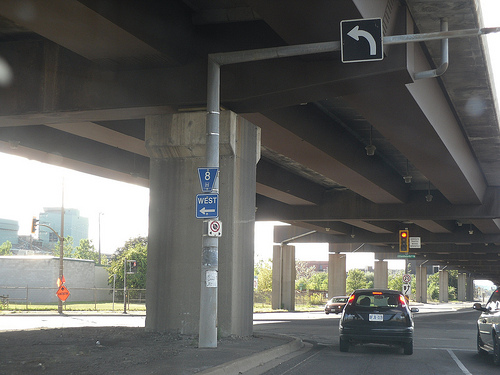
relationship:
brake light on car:
[390, 310, 415, 325] [321, 287, 452, 352]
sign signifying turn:
[334, 17, 389, 61] [438, 281, 498, 297]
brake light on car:
[372, 291, 382, 295] [345, 297, 412, 346]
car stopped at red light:
[336, 282, 434, 359] [396, 225, 406, 240]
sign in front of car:
[207, 217, 224, 237] [335, 287, 415, 355]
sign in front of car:
[193, 189, 216, 219] [472, 285, 498, 363]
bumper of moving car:
[341, 325, 415, 334] [466, 283, 498, 360]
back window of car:
[354, 291, 405, 310] [335, 287, 415, 355]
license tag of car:
[369, 313, 386, 325] [322, 285, 418, 357]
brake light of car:
[372, 291, 384, 296] [339, 288, 414, 353]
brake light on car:
[398, 294, 406, 306] [320, 270, 428, 367]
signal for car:
[390, 216, 416, 257] [313, 267, 430, 354]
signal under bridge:
[399, 229, 409, 252] [2, 1, 499, 338]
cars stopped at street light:
[323, 287, 498, 368] [400, 227, 407, 239]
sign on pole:
[54, 276, 71, 304] [56, 249, 64, 273]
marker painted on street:
[428, 338, 477, 366] [402, 280, 470, 370]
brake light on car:
[347, 293, 355, 304] [335, 287, 415, 355]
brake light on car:
[372, 291, 382, 295] [335, 287, 415, 355]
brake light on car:
[398, 294, 406, 306] [335, 287, 415, 355]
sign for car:
[207, 217, 224, 237] [335, 287, 415, 355]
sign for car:
[207, 217, 224, 237] [472, 285, 498, 363]